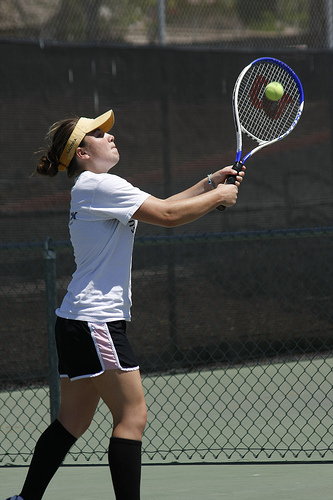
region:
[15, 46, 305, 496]
a woman playing tennis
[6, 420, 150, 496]
she is wearing black socks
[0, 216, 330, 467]
a black fence behind the woman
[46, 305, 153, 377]
she is wearing black shorts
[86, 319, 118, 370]
a pink strip on the shorts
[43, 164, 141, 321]
she is wearing a white shirt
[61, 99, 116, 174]
she is wearing a yellow cap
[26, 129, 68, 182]
her hair is in a bun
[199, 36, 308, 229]
both hands holding the tennis racket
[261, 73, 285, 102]
the ball is hitting the tennis racket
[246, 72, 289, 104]
this is a ball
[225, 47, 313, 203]
this is a racket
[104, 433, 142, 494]
this is a black sock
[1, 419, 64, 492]
this is a black sock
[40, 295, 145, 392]
the player is in shorts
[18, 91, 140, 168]
the lady is wearing a cap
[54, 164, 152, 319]
the lady is in a tee shirt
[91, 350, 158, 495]
the leg of a lady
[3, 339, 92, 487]
the leg of a lady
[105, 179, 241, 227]
the hand of a lady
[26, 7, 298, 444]
One woman is playing tennis.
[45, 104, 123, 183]
Cap is yellow color.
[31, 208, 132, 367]
woman is in white and black dress.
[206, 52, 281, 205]
Woman is holding tennis racket.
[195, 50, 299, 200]
Tennis racket is blue and white color.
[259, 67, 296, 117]
Ball is yellow color.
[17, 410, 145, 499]
Woman is wearing black socks.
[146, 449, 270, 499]
Ground is grey color.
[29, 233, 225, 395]
Fence is behind the player.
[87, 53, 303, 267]
Player is swinging the bat to hit the ball.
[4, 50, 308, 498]
Woman is playing tennis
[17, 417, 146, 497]
Woman is wearing socks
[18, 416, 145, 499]
Woman is wearing black socks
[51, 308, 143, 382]
Woman is wearing shorts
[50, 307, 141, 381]
Woman is wearing black, pink, and white shorts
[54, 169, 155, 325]
Woman is wearing a shirt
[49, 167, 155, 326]
Woman is wearing a white shirt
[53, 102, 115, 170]
Woman is wearing a visor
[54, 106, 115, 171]
Woman is wearing a yellow visor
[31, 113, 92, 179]
Woman has hair in a bun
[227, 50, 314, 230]
tennis bat with the ball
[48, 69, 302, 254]
a player holding tennis ball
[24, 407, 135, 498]
a tennis player wearing pair of socks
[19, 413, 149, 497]
black color socks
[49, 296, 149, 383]
black and cream color shorts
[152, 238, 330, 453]
a net in the tennis court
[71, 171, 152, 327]
a player wearing white color t-shirt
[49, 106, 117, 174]
a hat on the players head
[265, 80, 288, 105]
yellow color tennis ball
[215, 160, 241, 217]
black color handle of the bat